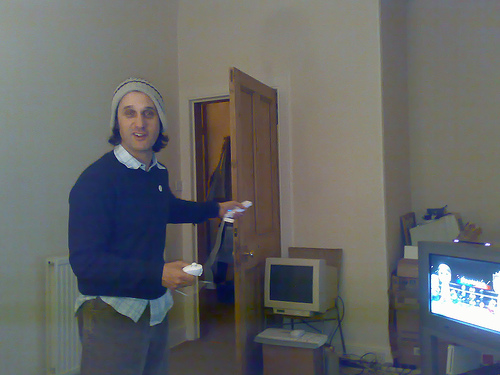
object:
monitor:
[262, 255, 340, 318]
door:
[228, 65, 283, 374]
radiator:
[40, 253, 83, 375]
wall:
[0, 0, 186, 375]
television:
[415, 237, 499, 357]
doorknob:
[241, 251, 250, 256]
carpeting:
[192, 66, 281, 375]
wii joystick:
[182, 261, 203, 277]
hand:
[161, 259, 196, 291]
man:
[63, 74, 249, 374]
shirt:
[66, 140, 220, 302]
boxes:
[394, 332, 425, 366]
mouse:
[290, 329, 308, 339]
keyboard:
[252, 327, 331, 349]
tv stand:
[415, 322, 500, 375]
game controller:
[223, 198, 253, 223]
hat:
[108, 75, 169, 137]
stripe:
[112, 79, 163, 100]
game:
[428, 251, 500, 335]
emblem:
[157, 184, 163, 192]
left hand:
[217, 200, 248, 219]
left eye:
[143, 109, 155, 119]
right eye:
[124, 109, 137, 118]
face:
[116, 89, 161, 151]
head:
[109, 76, 170, 153]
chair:
[252, 245, 344, 374]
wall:
[379, 0, 499, 276]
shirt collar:
[111, 142, 167, 173]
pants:
[73, 294, 172, 375]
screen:
[268, 263, 314, 305]